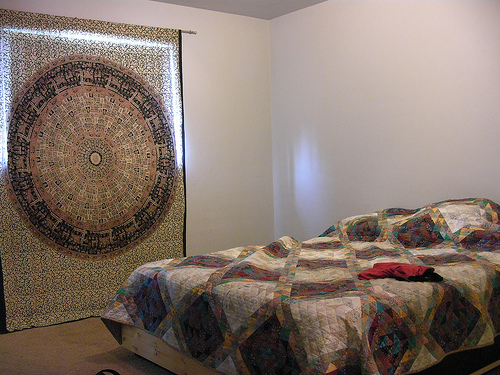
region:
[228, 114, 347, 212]
light is on the wall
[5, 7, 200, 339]
the window shade is long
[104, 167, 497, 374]
the bed is made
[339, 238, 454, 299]
a red garment on the bed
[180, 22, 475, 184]
the walls are white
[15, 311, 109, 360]
the floor is beige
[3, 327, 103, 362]
the floor is carpeted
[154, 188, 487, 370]
the blanket is multi colored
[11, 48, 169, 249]
a circle shape on the drape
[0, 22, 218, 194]
the sun is bright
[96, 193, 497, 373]
A large bed in the room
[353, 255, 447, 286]
A red piece of cloth on the bed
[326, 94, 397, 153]
Part of the wall in the room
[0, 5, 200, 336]
A curtain in the room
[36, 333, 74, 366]
Part of the floor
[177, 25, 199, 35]
Part of the curtain rod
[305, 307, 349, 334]
A white part on the comforter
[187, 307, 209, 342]
A dark part of the comforter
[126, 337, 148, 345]
Part of the base of the bed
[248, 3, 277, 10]
Part of the ceiling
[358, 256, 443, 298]
a red shirt on the bed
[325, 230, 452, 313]
a red shirt on the bed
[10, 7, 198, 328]
the curtain is closed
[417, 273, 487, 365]
triangles in square on bed cover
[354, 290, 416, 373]
triangles in square on bed cover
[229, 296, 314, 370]
triangles in square on bed cover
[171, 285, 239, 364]
triangles in square on bed cover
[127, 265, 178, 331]
triangles in square on bed cover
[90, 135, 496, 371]
king sized bed in room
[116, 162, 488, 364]
patterned cover on bed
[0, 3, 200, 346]
long brown window curtain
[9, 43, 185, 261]
circular design on curtain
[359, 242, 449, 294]
red cloth on bed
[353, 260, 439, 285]
red garment on the bed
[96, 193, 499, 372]
comforter covering the bed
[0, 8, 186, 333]
curtain covering the window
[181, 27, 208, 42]
curtain rod hung above the window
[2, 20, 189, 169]
light coming in through the window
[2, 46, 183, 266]
circular pattern on the window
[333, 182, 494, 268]
lump under the conforter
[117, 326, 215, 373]
wooden bed frame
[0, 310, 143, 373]
brown carpet covering the floor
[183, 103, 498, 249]
wall is painted white